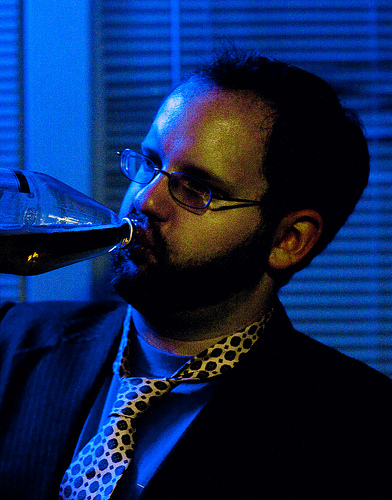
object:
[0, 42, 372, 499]
man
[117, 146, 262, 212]
glasses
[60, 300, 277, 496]
knot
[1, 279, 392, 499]
jacket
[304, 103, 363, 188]
hair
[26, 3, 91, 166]
wall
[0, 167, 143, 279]
bottle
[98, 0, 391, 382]
blind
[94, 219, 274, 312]
beard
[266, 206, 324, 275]
ear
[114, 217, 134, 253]
ring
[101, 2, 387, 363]
window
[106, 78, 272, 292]
face